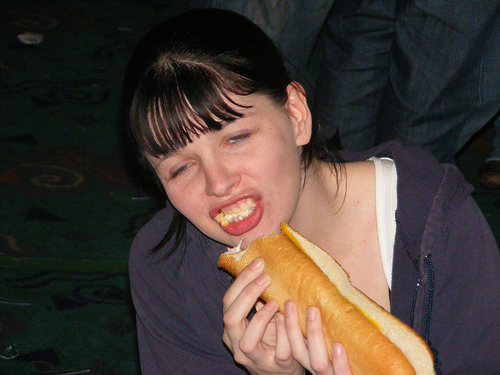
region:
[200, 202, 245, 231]
food in her mouth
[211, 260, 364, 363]
holding bun with two hands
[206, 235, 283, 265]
bite missing from bun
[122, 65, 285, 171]
girl is wearing bangs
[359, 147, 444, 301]
girl is wearing white t-shirt under her blue top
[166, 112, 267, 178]
woman is half closing her eyes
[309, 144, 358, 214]
pieces of hair on her neck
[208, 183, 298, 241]
woman is showing her teeth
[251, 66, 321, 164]
hair is behind her ears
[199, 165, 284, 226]
red marks on her face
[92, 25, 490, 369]
This is a person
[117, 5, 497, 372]
Girl eating huge hotdog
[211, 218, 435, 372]
Huge hotdog being eaten by girl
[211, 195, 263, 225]
Partial eaten bun stuck in teeth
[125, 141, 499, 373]
Blue sweater being worn by girl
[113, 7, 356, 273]
Girl has dark hair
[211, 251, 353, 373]
Girl's hands that are holding hot dog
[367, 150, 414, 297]
White shirt being worn by girl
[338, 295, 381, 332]
Mustard on hot dog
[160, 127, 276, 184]
Girl squinting her eyes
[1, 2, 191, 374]
Carpet that girl is sitting on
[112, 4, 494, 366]
Woman eating big sandwich.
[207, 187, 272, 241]
Food in woman's mouth.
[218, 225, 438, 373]
Big sandwich in woman's hands.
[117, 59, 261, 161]
Woman's dark bangs.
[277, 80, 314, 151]
Ear on woman's head.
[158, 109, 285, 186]
squinted eyes of woman eating.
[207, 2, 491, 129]
Pair of legs in background.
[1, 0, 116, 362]
Green patterned carpet.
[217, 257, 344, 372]
Fingers of woman's hands.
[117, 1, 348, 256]
Woman's dark hair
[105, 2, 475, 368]
a woman eating a sub sandwhich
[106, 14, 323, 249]
the head of a woman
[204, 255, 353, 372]
the hands of a woman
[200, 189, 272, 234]
the mouth of a woman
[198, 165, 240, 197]
the nose of a woman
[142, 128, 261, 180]
the eyes of a woman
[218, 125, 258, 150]
the eye of a woman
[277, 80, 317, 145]
the ear of a woman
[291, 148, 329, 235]
the neck of a woman